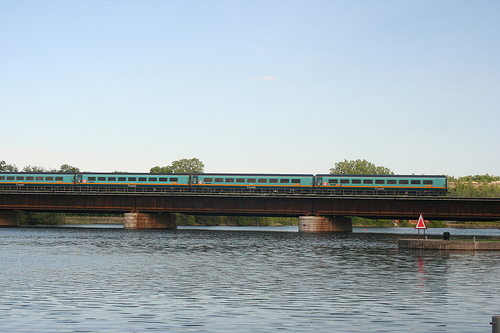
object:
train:
[1, 171, 447, 194]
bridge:
[2, 196, 499, 234]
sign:
[415, 212, 428, 229]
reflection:
[417, 257, 426, 275]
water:
[316, 307, 363, 333]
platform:
[397, 237, 499, 253]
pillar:
[123, 212, 178, 231]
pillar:
[298, 216, 354, 234]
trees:
[57, 164, 81, 173]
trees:
[172, 158, 204, 175]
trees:
[329, 158, 377, 177]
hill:
[448, 176, 499, 196]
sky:
[1, 0, 499, 179]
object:
[443, 231, 452, 242]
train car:
[1, 172, 77, 188]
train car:
[80, 172, 191, 186]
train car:
[192, 174, 314, 189]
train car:
[317, 176, 448, 191]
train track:
[1, 194, 500, 220]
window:
[329, 179, 339, 184]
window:
[340, 179, 351, 184]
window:
[352, 179, 362, 184]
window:
[363, 179, 373, 185]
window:
[387, 180, 398, 185]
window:
[88, 177, 97, 182]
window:
[98, 176, 107, 182]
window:
[108, 176, 117, 181]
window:
[117, 177, 126, 182]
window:
[169, 177, 180, 183]